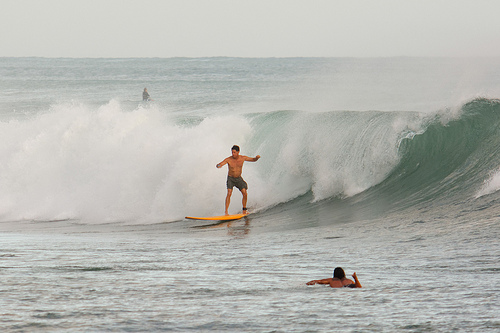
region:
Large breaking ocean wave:
[2, 90, 498, 222]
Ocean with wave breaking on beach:
[1, 53, 497, 330]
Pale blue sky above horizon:
[2, 0, 499, 56]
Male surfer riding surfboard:
[184, 142, 262, 223]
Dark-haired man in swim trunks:
[215, 144, 262, 217]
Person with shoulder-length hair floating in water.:
[306, 265, 364, 289]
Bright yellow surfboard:
[183, 212, 250, 222]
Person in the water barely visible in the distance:
[141, 85, 152, 102]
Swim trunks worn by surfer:
[226, 173, 248, 190]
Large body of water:
[1, 54, 498, 329]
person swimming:
[307, 261, 368, 301]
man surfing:
[188, 126, 265, 236]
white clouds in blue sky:
[18, 6, 43, 48]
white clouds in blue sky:
[61, 15, 123, 57]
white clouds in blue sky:
[162, 5, 197, 47]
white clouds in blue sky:
[222, 13, 259, 51]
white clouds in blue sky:
[307, 11, 338, 52]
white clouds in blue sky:
[371, 8, 431, 56]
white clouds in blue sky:
[424, 19, 465, 56]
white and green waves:
[42, 153, 113, 221]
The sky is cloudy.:
[8, 1, 498, 70]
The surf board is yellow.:
[173, 205, 257, 222]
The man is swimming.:
[300, 256, 365, 290]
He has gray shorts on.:
[224, 170, 261, 196]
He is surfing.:
[193, 135, 254, 231]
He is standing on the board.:
[169, 131, 281, 229]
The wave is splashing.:
[11, 93, 495, 238]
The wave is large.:
[29, 94, 499, 219]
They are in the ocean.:
[14, 28, 491, 324]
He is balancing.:
[170, 132, 281, 234]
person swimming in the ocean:
[306, 258, 370, 293]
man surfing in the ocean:
[187, 143, 267, 231]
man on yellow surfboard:
[180, 138, 262, 225]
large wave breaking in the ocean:
[271, 112, 386, 210]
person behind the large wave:
[134, 88, 157, 105]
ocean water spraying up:
[30, 117, 141, 217]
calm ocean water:
[69, 263, 193, 318]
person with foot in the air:
[304, 260, 364, 294]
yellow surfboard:
[184, 212, 258, 226]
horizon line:
[245, 48, 370, 71]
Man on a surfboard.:
[175, 120, 271, 249]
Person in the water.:
[270, 245, 368, 297]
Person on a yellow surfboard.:
[172, 135, 282, 248]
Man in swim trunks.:
[185, 127, 317, 251]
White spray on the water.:
[170, 105, 367, 225]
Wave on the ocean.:
[153, 77, 365, 237]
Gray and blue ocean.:
[260, 122, 402, 245]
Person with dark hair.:
[283, 235, 415, 299]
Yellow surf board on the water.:
[157, 207, 247, 238]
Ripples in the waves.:
[42, 216, 174, 289]